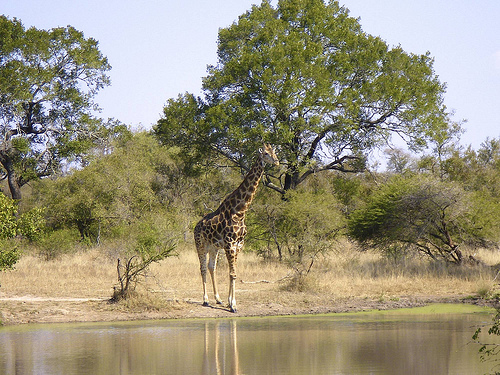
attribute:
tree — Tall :
[158, 12, 452, 204]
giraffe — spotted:
[182, 133, 301, 337]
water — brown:
[250, 332, 420, 365]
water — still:
[32, 321, 492, 372]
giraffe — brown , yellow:
[163, 135, 288, 338]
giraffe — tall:
[257, 141, 282, 166]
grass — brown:
[6, 244, 482, 310]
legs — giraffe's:
[198, 255, 247, 314]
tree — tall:
[218, 19, 380, 208]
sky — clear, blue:
[119, 23, 216, 113]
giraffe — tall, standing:
[193, 142, 282, 310]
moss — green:
[3, 299, 497, 329]